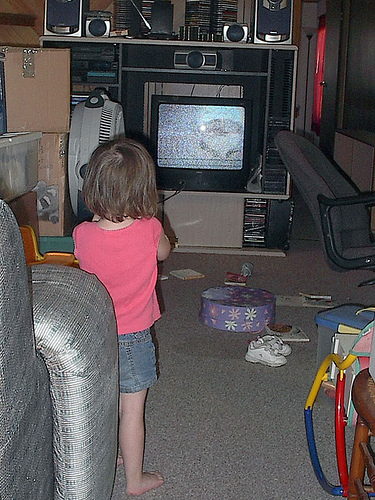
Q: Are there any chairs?
A: Yes, there is a chair.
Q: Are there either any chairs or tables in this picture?
A: Yes, there is a chair.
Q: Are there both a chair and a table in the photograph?
A: Yes, there are both a chair and a table.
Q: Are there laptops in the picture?
A: No, there are no laptops.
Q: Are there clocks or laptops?
A: No, there are no laptops or clocks.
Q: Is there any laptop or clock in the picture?
A: No, there are no laptops or clocks.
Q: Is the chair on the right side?
A: Yes, the chair is on the right of the image.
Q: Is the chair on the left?
A: No, the chair is on the right of the image.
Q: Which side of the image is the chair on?
A: The chair is on the right of the image.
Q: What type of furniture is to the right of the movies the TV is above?
A: The piece of furniture is a chair.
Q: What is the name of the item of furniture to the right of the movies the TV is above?
A: The piece of furniture is a chair.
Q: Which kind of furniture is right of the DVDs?
A: The piece of furniture is a chair.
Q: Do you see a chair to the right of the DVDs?
A: Yes, there is a chair to the right of the DVDs.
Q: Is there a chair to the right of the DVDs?
A: Yes, there is a chair to the right of the DVDs.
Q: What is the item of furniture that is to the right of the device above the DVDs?
A: The piece of furniture is a chair.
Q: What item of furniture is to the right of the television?
A: The piece of furniture is a chair.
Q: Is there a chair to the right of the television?
A: Yes, there is a chair to the right of the television.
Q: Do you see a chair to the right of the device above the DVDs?
A: Yes, there is a chair to the right of the television.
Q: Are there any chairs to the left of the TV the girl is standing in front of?
A: No, the chair is to the right of the television.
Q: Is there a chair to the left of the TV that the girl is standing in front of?
A: No, the chair is to the right of the television.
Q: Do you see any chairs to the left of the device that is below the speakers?
A: No, the chair is to the right of the television.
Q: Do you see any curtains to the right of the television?
A: No, there is a chair to the right of the television.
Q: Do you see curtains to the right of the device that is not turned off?
A: No, there is a chair to the right of the television.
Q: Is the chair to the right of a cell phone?
A: No, the chair is to the right of a television.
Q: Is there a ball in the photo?
A: No, there are no balls.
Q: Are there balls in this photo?
A: No, there are no balls.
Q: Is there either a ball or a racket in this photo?
A: No, there are no balls or rackets.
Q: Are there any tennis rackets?
A: No, there are no tennis rackets.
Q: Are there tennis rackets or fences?
A: No, there are no tennis rackets or fences.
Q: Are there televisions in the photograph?
A: Yes, there is a television.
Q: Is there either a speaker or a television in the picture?
A: Yes, there is a television.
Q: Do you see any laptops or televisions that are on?
A: Yes, the television is on.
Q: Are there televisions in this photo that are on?
A: Yes, there is a television that is on.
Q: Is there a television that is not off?
A: Yes, there is a television that is on.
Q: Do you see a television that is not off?
A: Yes, there is a television that is on .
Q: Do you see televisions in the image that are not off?
A: Yes, there is a television that is on .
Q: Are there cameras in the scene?
A: No, there are no cameras.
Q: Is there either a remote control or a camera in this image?
A: No, there are no cameras or remote controls.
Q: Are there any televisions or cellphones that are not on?
A: No, there is a television but it is on.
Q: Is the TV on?
A: Yes, the TV is on.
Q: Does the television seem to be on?
A: Yes, the television is on.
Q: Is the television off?
A: No, the television is on.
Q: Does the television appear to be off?
A: No, the television is on.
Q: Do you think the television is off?
A: No, the television is on.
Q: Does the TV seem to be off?
A: No, the TV is on.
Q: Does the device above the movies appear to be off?
A: No, the TV is on.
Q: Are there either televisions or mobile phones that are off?
A: No, there is a television but it is on.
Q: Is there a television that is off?
A: No, there is a television but it is on.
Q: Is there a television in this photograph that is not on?
A: No, there is a television but it is on.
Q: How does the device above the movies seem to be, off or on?
A: The TV is on.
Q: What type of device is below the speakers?
A: The device is a television.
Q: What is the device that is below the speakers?
A: The device is a television.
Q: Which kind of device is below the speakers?
A: The device is a television.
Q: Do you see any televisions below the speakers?
A: Yes, there is a television below the speakers.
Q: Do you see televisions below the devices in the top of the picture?
A: Yes, there is a television below the speakers.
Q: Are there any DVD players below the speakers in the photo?
A: No, there is a television below the speakers.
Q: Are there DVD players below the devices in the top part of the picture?
A: No, there is a television below the speakers.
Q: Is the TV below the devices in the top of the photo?
A: Yes, the TV is below the speakers.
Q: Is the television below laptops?
A: No, the television is below the speakers.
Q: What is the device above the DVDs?
A: The device is a television.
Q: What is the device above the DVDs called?
A: The device is a television.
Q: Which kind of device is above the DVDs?
A: The device is a television.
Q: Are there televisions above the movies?
A: Yes, there is a television above the movies.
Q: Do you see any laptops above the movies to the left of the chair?
A: No, there is a television above the DVDs.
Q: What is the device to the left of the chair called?
A: The device is a television.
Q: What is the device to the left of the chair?
A: The device is a television.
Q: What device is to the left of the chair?
A: The device is a television.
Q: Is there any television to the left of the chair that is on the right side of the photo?
A: Yes, there is a television to the left of the chair.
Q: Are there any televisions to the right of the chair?
A: No, the television is to the left of the chair.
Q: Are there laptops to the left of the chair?
A: No, there is a television to the left of the chair.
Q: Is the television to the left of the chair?
A: Yes, the television is to the left of the chair.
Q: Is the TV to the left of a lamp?
A: No, the TV is to the left of the chair.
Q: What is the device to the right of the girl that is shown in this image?
A: The device is a television.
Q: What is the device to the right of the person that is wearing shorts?
A: The device is a television.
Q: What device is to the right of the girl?
A: The device is a television.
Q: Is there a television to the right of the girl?
A: Yes, there is a television to the right of the girl.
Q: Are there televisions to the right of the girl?
A: Yes, there is a television to the right of the girl.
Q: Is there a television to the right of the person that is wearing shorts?
A: Yes, there is a television to the right of the girl.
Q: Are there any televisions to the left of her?
A: No, the television is to the right of the girl.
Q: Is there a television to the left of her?
A: No, the television is to the right of the girl.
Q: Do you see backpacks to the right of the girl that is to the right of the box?
A: No, there is a television to the right of the girl.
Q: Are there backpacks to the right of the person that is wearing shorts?
A: No, there is a television to the right of the girl.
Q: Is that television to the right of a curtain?
A: No, the television is to the right of a girl.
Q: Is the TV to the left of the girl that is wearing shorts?
A: No, the TV is to the right of the girl.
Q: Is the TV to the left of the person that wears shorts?
A: No, the TV is to the right of the girl.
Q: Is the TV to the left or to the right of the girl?
A: The TV is to the right of the girl.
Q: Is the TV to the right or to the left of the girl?
A: The TV is to the right of the girl.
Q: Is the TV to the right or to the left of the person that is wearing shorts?
A: The TV is to the right of the girl.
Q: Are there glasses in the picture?
A: No, there are no glasses.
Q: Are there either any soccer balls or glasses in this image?
A: No, there are no glasses or soccer balls.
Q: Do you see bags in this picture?
A: No, there are no bags.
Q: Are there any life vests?
A: No, there are no life vests.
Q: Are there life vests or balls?
A: No, there are no life vests or balls.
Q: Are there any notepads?
A: No, there are no notepads.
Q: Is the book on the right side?
A: Yes, the book is on the right of the image.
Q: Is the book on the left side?
A: No, the book is on the right of the image.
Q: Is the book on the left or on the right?
A: The book is on the right of the image.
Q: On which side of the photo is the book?
A: The book is on the right of the image.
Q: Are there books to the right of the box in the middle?
A: Yes, there is a book to the right of the box.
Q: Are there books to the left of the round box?
A: No, the book is to the right of the box.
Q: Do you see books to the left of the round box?
A: No, the book is to the right of the box.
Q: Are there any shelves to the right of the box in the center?
A: No, there is a book to the right of the box.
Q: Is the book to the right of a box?
A: Yes, the book is to the right of a box.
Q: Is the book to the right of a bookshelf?
A: No, the book is to the right of a box.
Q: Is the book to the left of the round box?
A: No, the book is to the right of the box.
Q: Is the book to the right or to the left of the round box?
A: The book is to the right of the box.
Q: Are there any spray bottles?
A: No, there are no spray bottles.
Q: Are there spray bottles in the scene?
A: No, there are no spray bottles.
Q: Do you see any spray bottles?
A: No, there are no spray bottles.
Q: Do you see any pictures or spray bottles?
A: No, there are no spray bottles or pictures.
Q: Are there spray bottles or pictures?
A: No, there are no spray bottles or pictures.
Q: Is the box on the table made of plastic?
A: Yes, the box is made of plastic.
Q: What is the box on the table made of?
A: The box is made of plastic.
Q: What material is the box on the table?
A: The box is made of plastic.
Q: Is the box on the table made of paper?
A: No, the box is made of plastic.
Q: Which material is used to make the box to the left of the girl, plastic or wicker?
A: The box is made of plastic.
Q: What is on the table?
A: The box is on the table.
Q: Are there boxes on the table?
A: Yes, there is a box on the table.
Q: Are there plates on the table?
A: No, there is a box on the table.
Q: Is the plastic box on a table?
A: Yes, the box is on a table.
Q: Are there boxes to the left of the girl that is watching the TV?
A: Yes, there is a box to the left of the girl.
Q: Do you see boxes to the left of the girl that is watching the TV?
A: Yes, there is a box to the left of the girl.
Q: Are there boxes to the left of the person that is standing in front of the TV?
A: Yes, there is a box to the left of the girl.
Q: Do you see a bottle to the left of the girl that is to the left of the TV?
A: No, there is a box to the left of the girl.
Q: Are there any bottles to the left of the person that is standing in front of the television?
A: No, there is a box to the left of the girl.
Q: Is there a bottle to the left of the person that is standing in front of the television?
A: No, there is a box to the left of the girl.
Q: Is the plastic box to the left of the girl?
A: Yes, the box is to the left of the girl.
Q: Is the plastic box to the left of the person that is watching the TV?
A: Yes, the box is to the left of the girl.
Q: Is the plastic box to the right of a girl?
A: No, the box is to the left of a girl.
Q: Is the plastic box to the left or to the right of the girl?
A: The box is to the left of the girl.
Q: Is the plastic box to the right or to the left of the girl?
A: The box is to the left of the girl.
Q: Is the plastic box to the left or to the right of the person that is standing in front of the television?
A: The box is to the left of the girl.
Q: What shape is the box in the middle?
A: The box is round.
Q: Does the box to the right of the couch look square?
A: No, the box is round.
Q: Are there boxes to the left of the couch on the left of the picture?
A: No, the box is to the right of the couch.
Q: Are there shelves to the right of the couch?
A: No, there is a box to the right of the couch.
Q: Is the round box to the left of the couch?
A: No, the box is to the right of the couch.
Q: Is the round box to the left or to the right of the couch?
A: The box is to the right of the couch.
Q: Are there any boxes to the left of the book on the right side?
A: Yes, there is a box to the left of the book.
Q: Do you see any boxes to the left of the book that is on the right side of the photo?
A: Yes, there is a box to the left of the book.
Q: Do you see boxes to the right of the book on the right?
A: No, the box is to the left of the book.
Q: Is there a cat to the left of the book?
A: No, there is a box to the left of the book.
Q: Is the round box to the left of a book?
A: Yes, the box is to the left of a book.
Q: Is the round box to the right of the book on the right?
A: No, the box is to the left of the book.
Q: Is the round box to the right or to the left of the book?
A: The box is to the left of the book.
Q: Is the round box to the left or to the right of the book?
A: The box is to the left of the book.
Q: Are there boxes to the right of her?
A: Yes, there is a box to the right of the girl.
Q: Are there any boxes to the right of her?
A: Yes, there is a box to the right of the girl.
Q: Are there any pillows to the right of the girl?
A: No, there is a box to the right of the girl.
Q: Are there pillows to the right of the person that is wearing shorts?
A: No, there is a box to the right of the girl.